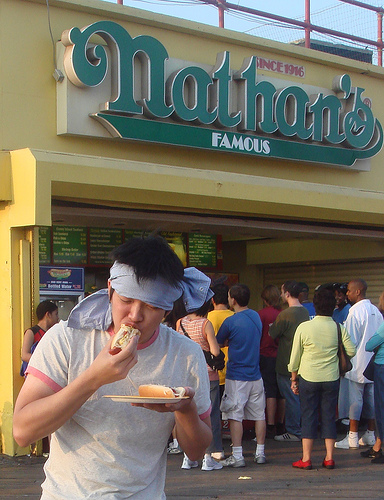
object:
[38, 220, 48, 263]
signs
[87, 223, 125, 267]
signs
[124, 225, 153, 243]
signs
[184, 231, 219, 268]
signs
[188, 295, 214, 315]
head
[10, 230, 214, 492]
man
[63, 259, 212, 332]
cloth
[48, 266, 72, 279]
hot dog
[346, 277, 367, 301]
head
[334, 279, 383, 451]
person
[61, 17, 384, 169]
sign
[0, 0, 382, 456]
building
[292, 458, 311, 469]
red shoe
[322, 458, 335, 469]
red shoe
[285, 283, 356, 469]
woman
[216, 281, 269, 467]
man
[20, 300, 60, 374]
man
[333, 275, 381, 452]
man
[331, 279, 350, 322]
woman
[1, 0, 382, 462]
nathan's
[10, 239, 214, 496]
people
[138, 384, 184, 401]
food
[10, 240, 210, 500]
person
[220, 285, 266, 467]
man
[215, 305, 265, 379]
shirt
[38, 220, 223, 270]
menu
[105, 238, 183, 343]
head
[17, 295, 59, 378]
perosn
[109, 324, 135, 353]
hotdog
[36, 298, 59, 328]
head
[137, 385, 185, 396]
sandwich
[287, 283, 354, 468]
person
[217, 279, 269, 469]
person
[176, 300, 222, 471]
person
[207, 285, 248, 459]
person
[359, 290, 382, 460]
person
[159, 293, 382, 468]
line